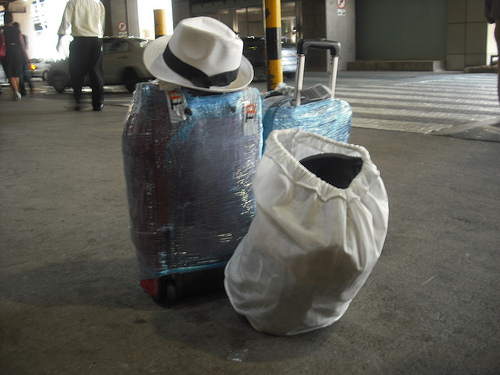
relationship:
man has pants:
[54, 2, 120, 119] [65, 37, 109, 112]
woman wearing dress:
[0, 15, 34, 103] [2, 25, 30, 75]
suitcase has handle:
[258, 37, 353, 165] [290, 32, 347, 114]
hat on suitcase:
[139, 8, 254, 103] [118, 71, 261, 343]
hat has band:
[139, 8, 254, 103] [164, 49, 235, 95]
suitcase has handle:
[258, 26, 363, 164] [290, 32, 347, 114]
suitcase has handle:
[118, 71, 261, 343] [290, 32, 347, 114]